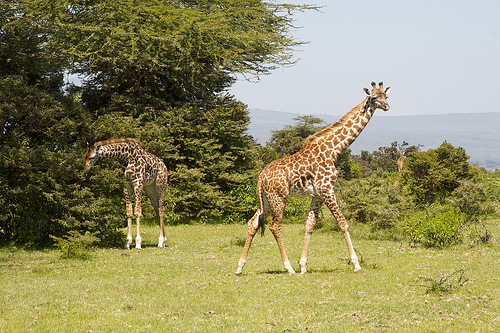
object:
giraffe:
[234, 80, 391, 275]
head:
[362, 81, 392, 111]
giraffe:
[83, 137, 168, 250]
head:
[77, 140, 101, 174]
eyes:
[385, 96, 390, 99]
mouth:
[384, 107, 389, 111]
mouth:
[83, 169, 90, 173]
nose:
[385, 105, 390, 109]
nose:
[82, 169, 87, 172]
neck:
[328, 95, 376, 157]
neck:
[95, 137, 132, 164]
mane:
[302, 96, 369, 149]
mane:
[94, 138, 140, 146]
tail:
[256, 180, 266, 238]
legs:
[264, 191, 296, 274]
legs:
[131, 182, 142, 251]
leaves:
[29, 7, 259, 90]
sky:
[0, 0, 498, 114]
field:
[0, 208, 499, 332]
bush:
[0, 0, 500, 261]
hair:
[255, 213, 267, 238]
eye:
[371, 97, 375, 100]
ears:
[362, 87, 371, 95]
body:
[262, 152, 328, 207]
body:
[112, 146, 163, 177]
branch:
[62, 16, 151, 44]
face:
[370, 89, 390, 112]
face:
[83, 149, 99, 173]